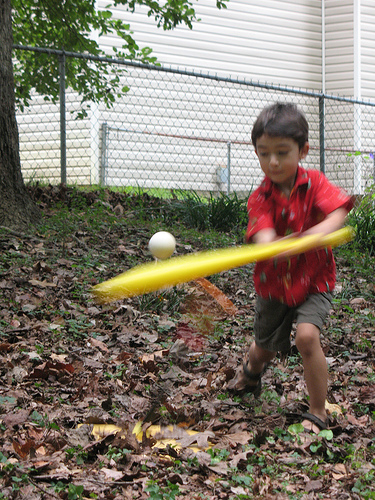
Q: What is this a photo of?
A: A boy playing a sport.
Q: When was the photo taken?
A: Daytime.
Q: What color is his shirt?
A: Red.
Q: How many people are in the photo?
A: One.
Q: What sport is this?
A: Baseball.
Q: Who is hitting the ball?
A: The boy.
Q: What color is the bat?
A: Yellow.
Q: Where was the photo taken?
A: In a backyard.